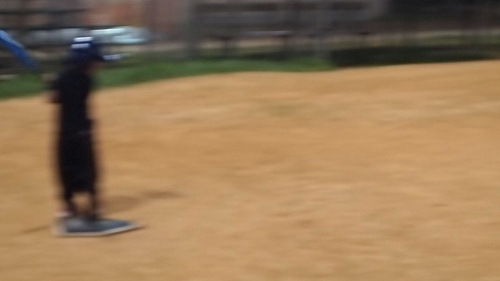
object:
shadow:
[15, 187, 184, 239]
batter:
[32, 50, 102, 223]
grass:
[0, 55, 341, 106]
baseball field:
[0, 35, 499, 58]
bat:
[0, 31, 45, 82]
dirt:
[0, 58, 499, 281]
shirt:
[40, 58, 103, 132]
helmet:
[59, 30, 110, 68]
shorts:
[52, 126, 105, 197]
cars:
[14, 25, 151, 50]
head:
[64, 50, 110, 76]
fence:
[0, 0, 499, 83]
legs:
[79, 140, 101, 209]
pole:
[186, 0, 201, 60]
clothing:
[40, 71, 103, 192]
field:
[0, 52, 499, 280]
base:
[50, 213, 143, 236]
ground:
[0, 60, 499, 280]